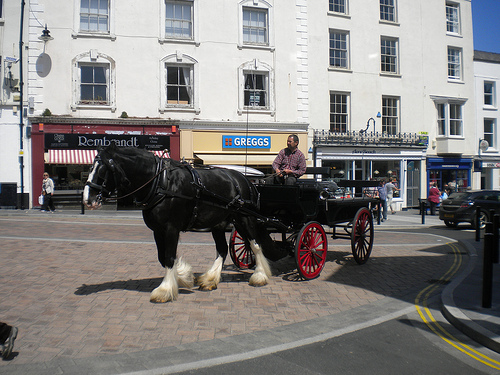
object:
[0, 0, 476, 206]
building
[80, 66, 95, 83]
windows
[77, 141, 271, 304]
horse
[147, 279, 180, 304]
hooves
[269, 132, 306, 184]
man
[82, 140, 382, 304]
carriage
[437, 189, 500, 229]
car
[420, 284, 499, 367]
lines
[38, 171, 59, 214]
woman